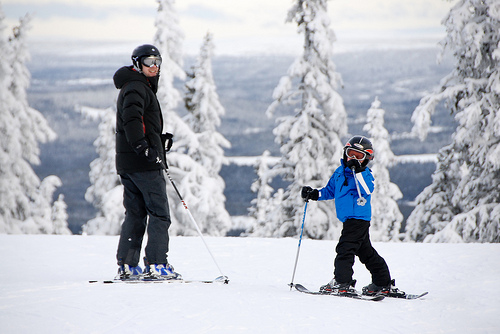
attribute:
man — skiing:
[113, 44, 184, 283]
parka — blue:
[317, 163, 376, 221]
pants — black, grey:
[116, 165, 174, 266]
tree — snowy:
[408, 0, 499, 242]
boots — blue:
[118, 261, 184, 280]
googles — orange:
[346, 147, 367, 163]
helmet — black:
[342, 134, 374, 163]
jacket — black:
[112, 65, 170, 174]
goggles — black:
[140, 55, 164, 69]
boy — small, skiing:
[302, 136, 395, 297]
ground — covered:
[0, 233, 499, 332]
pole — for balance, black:
[156, 156, 232, 283]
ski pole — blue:
[287, 186, 312, 291]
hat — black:
[129, 44, 161, 66]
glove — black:
[299, 185, 319, 200]